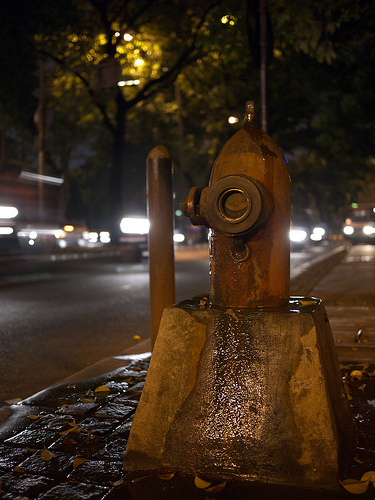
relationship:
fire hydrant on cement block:
[179, 101, 296, 307] [122, 292, 362, 489]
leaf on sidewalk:
[92, 382, 111, 392] [1, 253, 373, 491]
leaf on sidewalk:
[25, 412, 39, 420] [1, 253, 373, 491]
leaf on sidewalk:
[51, 413, 82, 438] [1, 253, 373, 491]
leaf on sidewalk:
[348, 368, 364, 381] [1, 253, 373, 491]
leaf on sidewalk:
[337, 477, 372, 494] [1, 253, 373, 491]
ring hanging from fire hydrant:
[229, 239, 253, 265] [120, 98, 359, 492]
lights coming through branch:
[115, 33, 163, 90] [42, 47, 111, 139]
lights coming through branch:
[115, 33, 163, 90] [98, 11, 124, 103]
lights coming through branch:
[115, 33, 163, 90] [129, 17, 220, 109]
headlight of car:
[340, 222, 354, 236] [339, 204, 373, 243]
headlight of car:
[362, 222, 374, 234] [339, 204, 373, 243]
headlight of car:
[289, 223, 307, 243] [291, 208, 313, 250]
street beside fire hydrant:
[1, 238, 349, 405] [120, 98, 359, 492]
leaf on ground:
[337, 477, 372, 494] [25, 240, 106, 327]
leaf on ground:
[188, 471, 210, 488] [25, 240, 106, 327]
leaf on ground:
[40, 443, 52, 461] [25, 240, 106, 327]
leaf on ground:
[93, 385, 110, 395] [25, 240, 106, 327]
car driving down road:
[289, 215, 308, 253] [0, 243, 343, 408]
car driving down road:
[340, 206, 374, 241] [0, 243, 343, 408]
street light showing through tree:
[113, 27, 135, 47] [28, 4, 140, 217]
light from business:
[117, 212, 151, 233] [2, 138, 66, 222]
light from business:
[121, 28, 133, 44] [2, 138, 66, 222]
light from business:
[286, 226, 308, 245] [2, 138, 66, 222]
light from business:
[341, 225, 354, 235] [2, 138, 66, 222]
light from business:
[2, 203, 20, 223] [2, 138, 66, 222]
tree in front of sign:
[0, 3, 261, 251] [35, 55, 126, 223]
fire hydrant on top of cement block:
[171, 85, 297, 310] [11, 259, 363, 361]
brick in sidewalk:
[8, 407, 81, 454] [28, 255, 371, 482]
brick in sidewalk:
[36, 478, 111, 498] [1, 253, 373, 491]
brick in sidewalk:
[2, 469, 59, 499] [6, 336, 373, 498]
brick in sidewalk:
[124, 375, 151, 391] [1, 253, 373, 491]